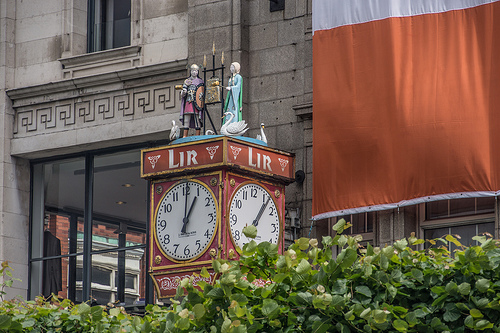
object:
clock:
[154, 179, 218, 260]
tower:
[208, 175, 219, 186]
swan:
[219, 111, 248, 137]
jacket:
[332, 82, 381, 106]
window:
[88, 249, 143, 303]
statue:
[179, 63, 208, 138]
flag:
[312, 2, 499, 222]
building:
[0, 0, 497, 313]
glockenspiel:
[201, 68, 222, 133]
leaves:
[283, 268, 320, 295]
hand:
[181, 175, 196, 234]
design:
[131, 86, 179, 114]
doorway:
[24, 158, 72, 299]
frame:
[103, 139, 143, 149]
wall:
[9, 3, 73, 62]